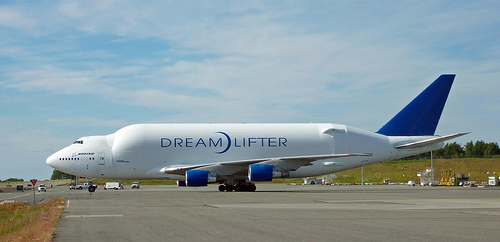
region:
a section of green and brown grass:
[0, 197, 65, 238]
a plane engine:
[241, 160, 286, 185]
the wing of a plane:
[190, 145, 370, 170]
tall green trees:
[460, 137, 496, 155]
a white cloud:
[4, 63, 139, 95]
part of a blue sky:
[122, 41, 154, 51]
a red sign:
[29, 177, 41, 201]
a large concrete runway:
[60, 172, 498, 240]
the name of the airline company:
[157, 134, 291, 151]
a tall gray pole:
[360, 164, 367, 184]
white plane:
[47, 47, 472, 184]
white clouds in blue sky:
[24, 25, 126, 85]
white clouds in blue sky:
[101, 32, 133, 81]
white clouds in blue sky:
[152, 21, 235, 117]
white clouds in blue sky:
[238, 17, 276, 85]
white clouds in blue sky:
[300, 36, 327, 102]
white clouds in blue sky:
[39, 38, 77, 100]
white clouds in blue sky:
[97, 32, 148, 111]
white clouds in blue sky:
[221, 4, 285, 98]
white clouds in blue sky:
[311, 27, 341, 80]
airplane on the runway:
[11, 47, 461, 211]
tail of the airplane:
[383, 60, 460, 130]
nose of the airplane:
[36, 132, 130, 192]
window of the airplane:
[59, 153, 64, 162]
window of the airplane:
[88, 155, 92, 160]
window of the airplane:
[99, 151, 106, 160]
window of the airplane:
[83, 148, 85, 155]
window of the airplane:
[64, 154, 70, 163]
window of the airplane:
[58, 152, 67, 163]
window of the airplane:
[66, 155, 73, 162]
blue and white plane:
[46, 69, 446, 194]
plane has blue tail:
[379, 62, 455, 133]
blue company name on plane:
[120, 91, 299, 163]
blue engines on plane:
[177, 152, 309, 184]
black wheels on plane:
[193, 158, 268, 196]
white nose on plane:
[54, 139, 86, 184]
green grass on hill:
[356, 155, 497, 197]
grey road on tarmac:
[126, 182, 463, 240]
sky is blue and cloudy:
[36, 17, 220, 109]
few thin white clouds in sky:
[70, 21, 220, 109]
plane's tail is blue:
[373, 67, 470, 150]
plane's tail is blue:
[366, 57, 478, 177]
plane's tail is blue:
[341, 55, 480, 175]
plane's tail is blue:
[368, 48, 487, 168]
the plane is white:
[33, 50, 463, 192]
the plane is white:
[18, 103, 443, 209]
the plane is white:
[26, 114, 445, 208]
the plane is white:
[22, 120, 482, 223]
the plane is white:
[21, 99, 449, 200]